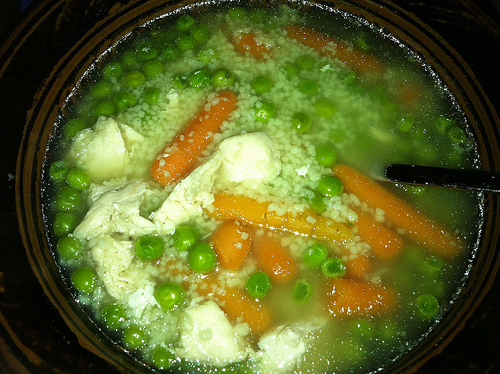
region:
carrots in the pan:
[173, 91, 235, 186]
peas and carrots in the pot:
[263, 55, 448, 330]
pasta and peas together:
[125, 26, 265, 152]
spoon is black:
[379, 149, 498, 204]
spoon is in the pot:
[359, 150, 494, 190]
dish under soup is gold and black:
[10, 46, 47, 367]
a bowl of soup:
[24, 145, 472, 360]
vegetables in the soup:
[55, 94, 412, 359]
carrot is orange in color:
[159, 91, 229, 176]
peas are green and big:
[44, 181, 234, 272]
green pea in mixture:
[185, 244, 215, 274]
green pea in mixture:
[152, 283, 184, 310]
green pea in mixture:
[322, 262, 347, 276]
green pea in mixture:
[176, 236, 195, 251]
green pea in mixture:
[58, 237, 84, 267]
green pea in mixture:
[413, 293, 439, 320]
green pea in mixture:
[66, 173, 87, 190]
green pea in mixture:
[123, 69, 151, 93]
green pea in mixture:
[138, 343, 173, 367]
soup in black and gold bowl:
[6, 3, 496, 372]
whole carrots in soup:
[165, 32, 444, 245]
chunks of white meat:
[77, 121, 279, 239]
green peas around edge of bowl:
[30, 156, 165, 361]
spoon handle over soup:
[373, 152, 498, 212]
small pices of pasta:
[235, 62, 355, 199]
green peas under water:
[95, 14, 202, 115]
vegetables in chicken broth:
[337, 22, 464, 159]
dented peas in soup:
[293, 256, 348, 303]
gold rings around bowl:
[12, 3, 494, 372]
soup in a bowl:
[10, 12, 485, 357]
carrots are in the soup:
[40, 2, 480, 369]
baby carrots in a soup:
[10, 18, 450, 310]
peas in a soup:
[47, 26, 492, 348]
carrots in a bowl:
[33, 22, 492, 369]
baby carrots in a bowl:
[23, 6, 465, 365]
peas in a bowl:
[10, 19, 460, 371]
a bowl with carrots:
[18, 20, 463, 371]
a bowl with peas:
[26, 11, 499, 360]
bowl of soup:
[6, 0, 497, 369]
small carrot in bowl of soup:
[139, 81, 245, 186]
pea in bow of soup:
[313, 166, 346, 200]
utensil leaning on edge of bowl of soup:
[388, 150, 497, 199]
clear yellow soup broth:
[354, 140, 374, 163]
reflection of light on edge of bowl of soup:
[353, 16, 423, 90]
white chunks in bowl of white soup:
[65, 115, 145, 185]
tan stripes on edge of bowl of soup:
[2, 32, 99, 339]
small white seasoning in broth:
[241, 95, 271, 124]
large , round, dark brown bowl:
[2, 0, 498, 367]